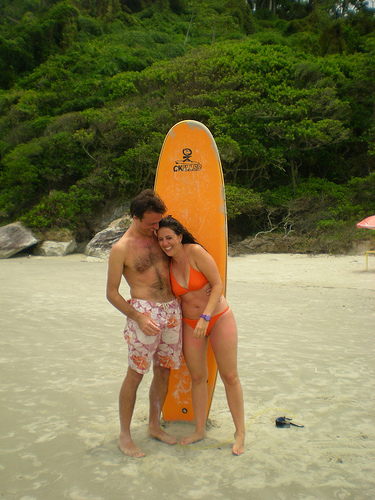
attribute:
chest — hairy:
[129, 239, 169, 277]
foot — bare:
[231, 428, 245, 458]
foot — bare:
[180, 430, 207, 446]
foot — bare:
[145, 425, 177, 446]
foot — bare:
[114, 432, 145, 459]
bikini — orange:
[164, 242, 230, 337]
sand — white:
[0, 252, 374, 498]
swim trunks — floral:
[124, 297, 181, 374]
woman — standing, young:
[155, 215, 247, 454]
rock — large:
[23, 237, 77, 254]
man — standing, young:
[106, 188, 181, 457]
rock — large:
[1, 219, 45, 258]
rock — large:
[35, 237, 76, 255]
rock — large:
[83, 212, 133, 259]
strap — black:
[275, 413, 305, 427]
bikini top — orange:
[169, 243, 207, 296]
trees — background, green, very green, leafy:
[3, 1, 372, 185]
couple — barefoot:
[100, 191, 264, 472]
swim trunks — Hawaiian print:
[109, 296, 201, 387]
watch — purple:
[196, 312, 219, 325]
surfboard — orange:
[150, 114, 234, 439]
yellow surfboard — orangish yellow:
[131, 115, 261, 428]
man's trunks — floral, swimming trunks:
[126, 298, 192, 380]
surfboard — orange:
[127, 109, 240, 420]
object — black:
[268, 413, 311, 438]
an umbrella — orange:
[350, 213, 374, 231]